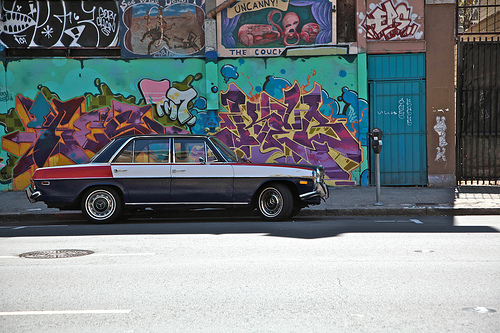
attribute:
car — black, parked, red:
[27, 133, 330, 223]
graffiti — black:
[1, 76, 369, 187]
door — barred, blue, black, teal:
[366, 52, 430, 187]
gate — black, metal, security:
[460, 1, 498, 185]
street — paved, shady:
[0, 224, 499, 332]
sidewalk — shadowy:
[3, 188, 500, 225]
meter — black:
[368, 127, 387, 207]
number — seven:
[166, 89, 198, 127]